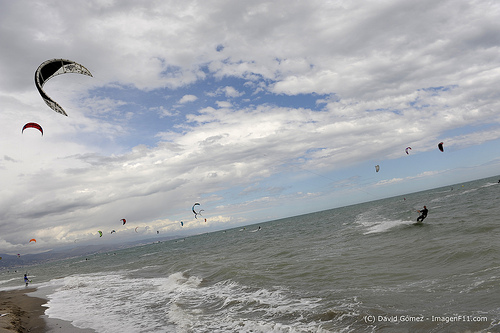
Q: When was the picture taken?
A: Daytime.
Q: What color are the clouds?
A: White.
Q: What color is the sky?
A: Blue.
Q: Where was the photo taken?
A: The ocean.